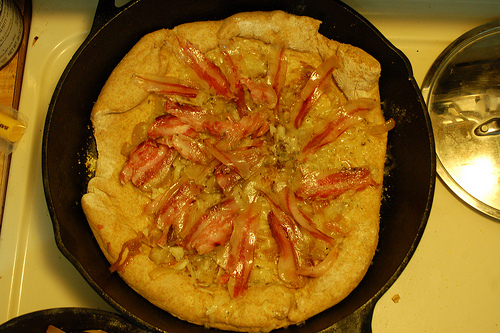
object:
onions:
[292, 248, 341, 277]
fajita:
[84, 10, 389, 330]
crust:
[194, 5, 328, 34]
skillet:
[41, 2, 441, 332]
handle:
[324, 304, 376, 332]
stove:
[6, 4, 499, 325]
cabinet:
[4, 4, 29, 208]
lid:
[422, 19, 500, 221]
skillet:
[1, 306, 143, 331]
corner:
[5, 217, 134, 332]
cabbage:
[162, 243, 192, 270]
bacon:
[223, 203, 261, 299]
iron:
[388, 176, 428, 229]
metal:
[453, 55, 500, 85]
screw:
[475, 124, 490, 134]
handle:
[471, 118, 500, 137]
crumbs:
[391, 293, 404, 301]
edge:
[2, 297, 140, 322]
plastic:
[1, 121, 24, 138]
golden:
[197, 295, 275, 318]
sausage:
[142, 112, 189, 140]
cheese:
[270, 122, 298, 151]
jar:
[3, 5, 26, 66]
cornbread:
[82, 11, 383, 332]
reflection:
[457, 153, 495, 187]